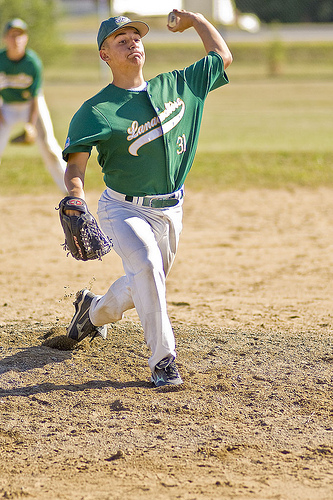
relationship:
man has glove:
[54, 8, 234, 387] [59, 186, 110, 264]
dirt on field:
[183, 315, 316, 395] [15, 199, 323, 485]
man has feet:
[54, 8, 234, 387] [150, 357, 182, 388]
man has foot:
[54, 8, 234, 387] [65, 286, 99, 350]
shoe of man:
[150, 356, 182, 387] [0, 17, 68, 191]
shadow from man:
[2, 340, 143, 408] [59, 7, 235, 380]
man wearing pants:
[59, 7, 235, 380] [88, 185, 186, 368]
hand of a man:
[164, 8, 193, 32] [54, 8, 234, 387]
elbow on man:
[63, 168, 84, 187] [54, 8, 234, 387]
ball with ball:
[168, 11, 177, 27] [168, 11, 177, 27]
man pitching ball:
[54, 8, 234, 387] [166, 10, 179, 27]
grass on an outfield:
[235, 148, 303, 172] [9, 32, 323, 151]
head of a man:
[83, 18, 145, 85] [54, 8, 234, 387]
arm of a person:
[153, 11, 233, 89] [36, 4, 236, 406]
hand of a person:
[167, 8, 190, 33] [72, 12, 197, 380]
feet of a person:
[38, 268, 228, 424] [36, 4, 236, 406]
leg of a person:
[99, 211, 184, 379] [72, 9, 209, 193]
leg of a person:
[94, 225, 178, 326] [72, 9, 209, 193]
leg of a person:
[19, 110, 66, 186] [5, 16, 61, 192]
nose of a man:
[129, 36, 139, 48] [54, 8, 234, 387]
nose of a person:
[11, 37, 18, 44] [3, 16, 63, 170]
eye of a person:
[115, 36, 128, 45] [52, 4, 243, 390]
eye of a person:
[132, 34, 146, 47] [52, 4, 243, 390]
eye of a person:
[10, 32, 14, 38] [7, 16, 66, 175]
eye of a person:
[16, 29, 23, 35] [7, 16, 66, 175]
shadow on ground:
[0, 332, 157, 395] [17, 326, 330, 498]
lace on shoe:
[158, 355, 172, 374] [144, 352, 186, 391]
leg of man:
[101, 209, 173, 353] [54, 8, 234, 387]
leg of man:
[65, 209, 183, 346] [54, 8, 234, 387]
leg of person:
[25, 102, 66, 187] [4, 18, 66, 200]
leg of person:
[94, 225, 178, 326] [110, 54, 262, 156]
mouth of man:
[127, 51, 143, 58] [54, 8, 234, 387]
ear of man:
[96, 45, 112, 66] [54, 8, 234, 387]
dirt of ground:
[0, 190, 331, 498] [0, 25, 331, 497]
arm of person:
[189, 11, 233, 101] [52, 4, 243, 390]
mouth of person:
[123, 49, 149, 68] [73, 17, 193, 128]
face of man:
[97, 20, 145, 69] [54, 8, 234, 387]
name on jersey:
[127, 99, 184, 155] [60, 51, 228, 198]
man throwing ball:
[59, 7, 235, 380] [164, 14, 226, 44]